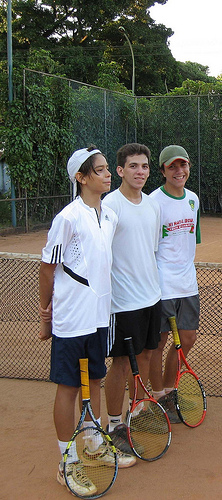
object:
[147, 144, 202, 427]
man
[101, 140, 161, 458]
man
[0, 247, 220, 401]
net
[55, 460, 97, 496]
shoe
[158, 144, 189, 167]
hat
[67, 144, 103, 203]
hat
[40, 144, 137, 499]
boy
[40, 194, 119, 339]
shirt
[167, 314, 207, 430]
raquet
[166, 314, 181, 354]
handle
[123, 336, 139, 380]
handle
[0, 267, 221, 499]
court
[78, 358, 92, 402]
handle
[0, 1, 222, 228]
forest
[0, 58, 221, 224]
fence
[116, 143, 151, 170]
hair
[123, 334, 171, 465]
racket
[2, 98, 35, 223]
ivy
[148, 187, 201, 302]
shirt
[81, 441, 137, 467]
shoe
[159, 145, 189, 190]
head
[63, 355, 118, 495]
racket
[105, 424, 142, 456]
shoe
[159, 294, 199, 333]
shorts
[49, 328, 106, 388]
shorts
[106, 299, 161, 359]
shorts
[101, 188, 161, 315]
shirt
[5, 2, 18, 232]
pole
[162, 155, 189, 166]
trim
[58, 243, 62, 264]
stripes